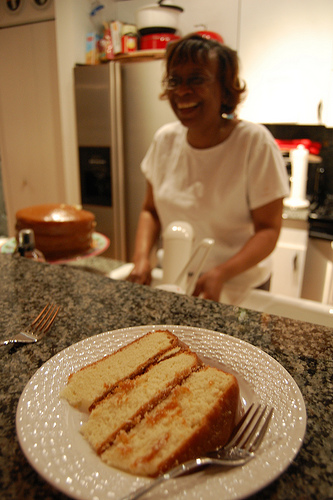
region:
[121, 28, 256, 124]
the woman is smiling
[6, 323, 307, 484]
plate of food on the table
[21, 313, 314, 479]
the plate is white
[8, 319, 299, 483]
the plate is round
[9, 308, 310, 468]
the plate has a design on it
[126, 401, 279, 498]
a fork is on the plate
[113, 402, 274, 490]
the fork is silver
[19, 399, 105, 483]
the light is on the plate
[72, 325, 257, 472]
cake is on the plate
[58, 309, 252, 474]
the cake is golden brown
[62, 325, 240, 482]
a slice of cake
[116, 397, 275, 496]
a fork on saucer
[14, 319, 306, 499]
a glistening saucer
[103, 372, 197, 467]
crumbs on top of slice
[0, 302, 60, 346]
a fork on counter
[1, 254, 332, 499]
a marble counter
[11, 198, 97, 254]
a chocolate iced cake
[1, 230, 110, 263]
a cake plate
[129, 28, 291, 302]
a lady standing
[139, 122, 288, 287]
a white shirt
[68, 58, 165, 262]
part of a refrigerator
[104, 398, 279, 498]
a long silver fork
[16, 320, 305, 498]
a white plate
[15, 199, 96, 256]
a large cake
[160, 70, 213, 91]
a woman's eyeglasses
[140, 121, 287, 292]
a woman's white shirt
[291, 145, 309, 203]
a white roll of paper towels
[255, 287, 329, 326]
part of a white sink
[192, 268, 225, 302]
part of a woman's hand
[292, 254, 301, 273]
a cabinet handle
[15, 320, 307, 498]
Piece of Cake already to eat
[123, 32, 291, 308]
Woman at Kitchen Sink Laughing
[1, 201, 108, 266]
Cake on Plate with Pieces Missing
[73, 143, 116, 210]
Water Dispenser in Refrigerator Door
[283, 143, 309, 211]
Paper Towel Rack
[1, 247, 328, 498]
Nice Granite Countertop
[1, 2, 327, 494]
Woman in Modern Kitchen Behind Counter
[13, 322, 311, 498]
Piece of Cake with Caramel Bits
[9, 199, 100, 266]
Cake with Caramel Icing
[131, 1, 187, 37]
White Crock Pot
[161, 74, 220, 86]
Eyeglasses on a woman.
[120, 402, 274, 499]
Metal fork on a white saucer.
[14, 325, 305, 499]
White saucer on counter top.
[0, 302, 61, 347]
Metal fork laying on counter top.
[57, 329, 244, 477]
Piece of cake on a white saucer.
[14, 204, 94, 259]
Three-layer cake with brown frosting.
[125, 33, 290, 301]
Smiling woman standing at sink.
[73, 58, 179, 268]
Grey refrigerator in a kitchen.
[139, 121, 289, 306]
White blouse on a woman.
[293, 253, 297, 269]
Metal knob on a cabinet door.